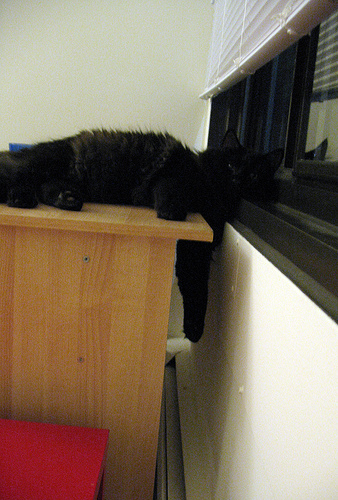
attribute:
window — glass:
[220, 30, 337, 142]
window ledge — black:
[204, 178, 336, 313]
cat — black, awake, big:
[0, 123, 287, 343]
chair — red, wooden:
[1, 414, 112, 498]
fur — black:
[53, 129, 238, 216]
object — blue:
[6, 137, 34, 156]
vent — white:
[159, 329, 208, 374]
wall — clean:
[0, 0, 226, 366]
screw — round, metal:
[71, 249, 103, 269]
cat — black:
[9, 126, 266, 222]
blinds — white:
[313, 24, 336, 94]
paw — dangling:
[173, 208, 214, 343]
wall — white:
[32, 23, 81, 77]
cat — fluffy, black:
[1, 118, 266, 220]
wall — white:
[182, 0, 336, 495]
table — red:
[0, 417, 110, 496]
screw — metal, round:
[76, 353, 83, 365]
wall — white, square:
[173, 213, 334, 496]